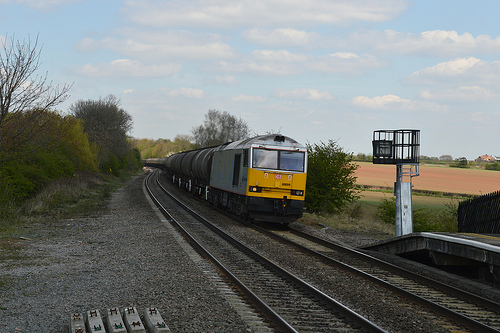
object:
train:
[165, 134, 307, 222]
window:
[252, 148, 278, 169]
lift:
[372, 129, 420, 234]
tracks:
[136, 156, 499, 332]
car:
[142, 133, 308, 227]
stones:
[4, 167, 256, 328]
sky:
[0, 1, 498, 161]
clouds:
[91, 0, 487, 111]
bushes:
[0, 28, 145, 213]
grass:
[379, 196, 459, 230]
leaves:
[48, 144, 78, 159]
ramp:
[359, 227, 499, 277]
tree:
[1, 31, 75, 162]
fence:
[452, 189, 500, 230]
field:
[345, 158, 499, 196]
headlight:
[249, 183, 261, 191]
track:
[161, 193, 256, 319]